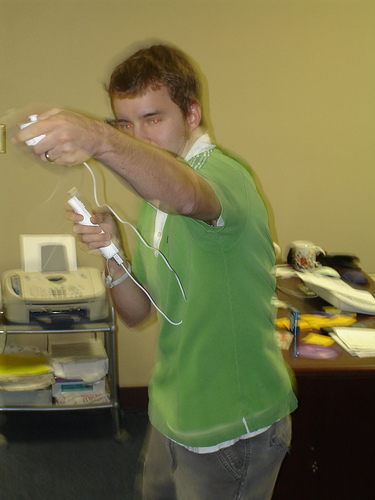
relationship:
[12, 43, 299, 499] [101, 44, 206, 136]
male has hair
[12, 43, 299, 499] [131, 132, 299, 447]
male wearing shirt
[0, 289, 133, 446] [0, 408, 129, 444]
cart one wheels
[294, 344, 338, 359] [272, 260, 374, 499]
cd on desk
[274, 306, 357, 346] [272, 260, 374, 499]
post it notes are on desk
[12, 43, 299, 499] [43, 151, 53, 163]
male wearing a wedding band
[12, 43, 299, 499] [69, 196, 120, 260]
male holding wiimote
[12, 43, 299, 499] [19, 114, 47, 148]
male holding nanchuck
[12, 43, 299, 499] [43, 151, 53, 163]
male wearing wedding band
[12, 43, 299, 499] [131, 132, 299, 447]
male wearing a shirt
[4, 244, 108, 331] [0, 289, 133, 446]
fax machine on cart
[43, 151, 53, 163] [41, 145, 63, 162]
wedding band on finger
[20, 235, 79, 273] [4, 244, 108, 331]
paper in fax machine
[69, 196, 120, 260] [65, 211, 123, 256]
wiimote in hand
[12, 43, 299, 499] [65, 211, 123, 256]
male has a hand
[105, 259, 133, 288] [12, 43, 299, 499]
wrist strap on male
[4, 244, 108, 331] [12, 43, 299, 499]
fax machine behind male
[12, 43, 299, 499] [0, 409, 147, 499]
male on floor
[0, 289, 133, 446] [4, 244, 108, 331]
cart under fax machine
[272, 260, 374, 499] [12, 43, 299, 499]
desk behind male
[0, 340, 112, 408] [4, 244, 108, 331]
reams of papers under fax machine